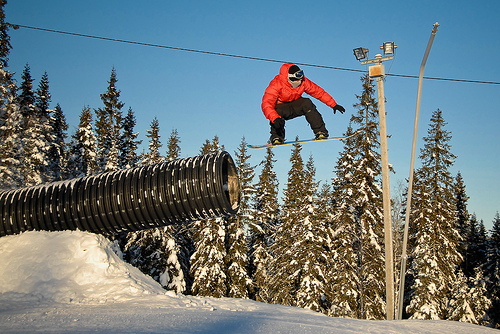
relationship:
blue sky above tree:
[0, 0, 499, 236] [5, 63, 44, 186]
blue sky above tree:
[0, 0, 499, 236] [68, 103, 96, 176]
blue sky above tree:
[0, 0, 499, 236] [95, 65, 122, 172]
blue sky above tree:
[0, 0, 499, 236] [330, 72, 387, 319]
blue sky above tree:
[0, 0, 499, 236] [409, 107, 466, 320]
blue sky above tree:
[0, 0, 499, 236] [334, 66, 390, 317]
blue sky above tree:
[0, 0, 499, 236] [277, 136, 305, 305]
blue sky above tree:
[0, 0, 499, 236] [252, 143, 277, 299]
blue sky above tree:
[0, 0, 499, 236] [97, 62, 121, 151]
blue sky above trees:
[0, 0, 499, 236] [5, 0, 496, 328]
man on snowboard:
[257, 60, 348, 145] [246, 130, 361, 150]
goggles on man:
[286, 69, 309, 81] [260, 62, 345, 145]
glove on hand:
[329, 101, 345, 113] [332, 103, 344, 115]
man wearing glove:
[260, 62, 345, 145] [329, 101, 345, 113]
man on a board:
[260, 62, 345, 145] [240, 128, 343, 149]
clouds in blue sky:
[3, 1, 498, 235] [0, 0, 499, 236]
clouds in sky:
[3, 1, 498, 235] [39, 6, 496, 76]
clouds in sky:
[3, 1, 498, 235] [135, 54, 256, 113]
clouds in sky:
[3, 1, 498, 235] [160, 5, 225, 37]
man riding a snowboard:
[257, 60, 348, 145] [246, 130, 361, 150]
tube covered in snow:
[2, 152, 238, 237] [5, 152, 218, 227]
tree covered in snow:
[402, 113, 485, 331] [412, 304, 442, 318]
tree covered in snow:
[396, 107, 464, 325] [405, 106, 476, 323]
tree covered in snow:
[307, 75, 389, 322] [316, 72, 395, 322]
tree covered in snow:
[23, 86, 49, 183] [123, 116, 183, 291]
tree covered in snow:
[68, 103, 96, 176] [63, 99, 98, 172]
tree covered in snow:
[123, 115, 183, 292] [18, 72, 60, 179]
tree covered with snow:
[294, 152, 337, 302] [301, 210, 313, 232]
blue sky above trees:
[0, 0, 499, 236] [3, 65, 497, 317]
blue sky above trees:
[0, 0, 499, 236] [5, 46, 427, 318]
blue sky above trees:
[0, 0, 499, 236] [0, 87, 473, 302]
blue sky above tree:
[0, 0, 499, 236] [411, 106, 475, 318]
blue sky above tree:
[0, 0, 499, 236] [321, 60, 386, 324]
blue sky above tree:
[0, 0, 499, 236] [277, 134, 309, 302]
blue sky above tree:
[0, 0, 499, 236] [252, 130, 281, 305]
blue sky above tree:
[0, 0, 499, 236] [222, 138, 258, 295]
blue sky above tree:
[0, 0, 499, 236] [395, 110, 467, 319]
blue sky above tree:
[0, 0, 499, 236] [267, 136, 314, 301]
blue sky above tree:
[0, 0, 499, 236] [225, 135, 257, 299]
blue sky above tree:
[0, 0, 499, 236] [93, 65, 119, 165]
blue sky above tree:
[0, 0, 499, 236] [402, 106, 475, 323]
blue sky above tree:
[0, 0, 499, 236] [272, 138, 306, 304]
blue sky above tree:
[0, 0, 499, 236] [291, 178, 333, 308]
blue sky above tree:
[0, 0, 499, 236] [257, 143, 275, 315]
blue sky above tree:
[0, 0, 499, 236] [227, 140, 254, 299]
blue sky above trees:
[0, 0, 499, 236] [128, 106, 388, 324]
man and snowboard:
[257, 60, 348, 145] [245, 129, 362, 151]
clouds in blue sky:
[3, 1, 498, 235] [0, 0, 499, 212]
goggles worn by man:
[286, 69, 309, 81] [257, 60, 348, 145]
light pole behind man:
[350, 40, 407, 317] [258, 62, 342, 142]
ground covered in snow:
[1, 232, 473, 331] [1, 231, 491, 331]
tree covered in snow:
[188, 136, 255, 298] [188, 135, 252, 297]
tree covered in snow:
[77, 70, 184, 170] [1, 231, 491, 331]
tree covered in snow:
[3, 73, 70, 195] [12, 122, 62, 161]